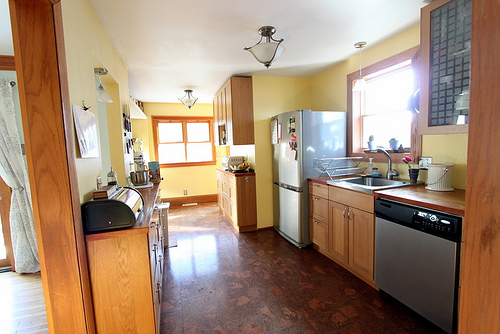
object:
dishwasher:
[373, 197, 462, 330]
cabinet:
[327, 200, 374, 281]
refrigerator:
[271, 110, 348, 250]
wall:
[257, 85, 270, 100]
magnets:
[287, 117, 297, 152]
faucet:
[386, 160, 398, 179]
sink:
[343, 176, 394, 187]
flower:
[401, 156, 413, 169]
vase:
[408, 169, 419, 182]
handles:
[342, 209, 350, 220]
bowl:
[130, 170, 149, 185]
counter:
[148, 192, 154, 201]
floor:
[237, 246, 259, 281]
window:
[158, 122, 213, 162]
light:
[243, 29, 285, 69]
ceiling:
[151, 30, 204, 68]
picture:
[73, 104, 102, 158]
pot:
[426, 164, 455, 191]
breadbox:
[116, 198, 134, 219]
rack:
[314, 157, 367, 177]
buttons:
[412, 211, 454, 234]